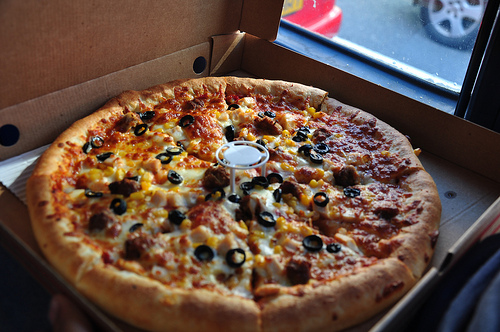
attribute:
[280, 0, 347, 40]
car — red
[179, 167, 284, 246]
pizza — cheesy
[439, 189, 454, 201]
spot — grease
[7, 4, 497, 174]
box — cardboard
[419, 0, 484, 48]
tire — black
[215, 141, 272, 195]
object — plastic, white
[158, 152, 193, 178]
olives — black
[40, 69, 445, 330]
pizza — cut into slices, olive, chees, thick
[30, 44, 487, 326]
pizza — cut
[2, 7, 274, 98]
box — cardboard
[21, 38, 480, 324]
box — cardboard, brown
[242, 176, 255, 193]
olive — black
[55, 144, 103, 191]
sauce — red